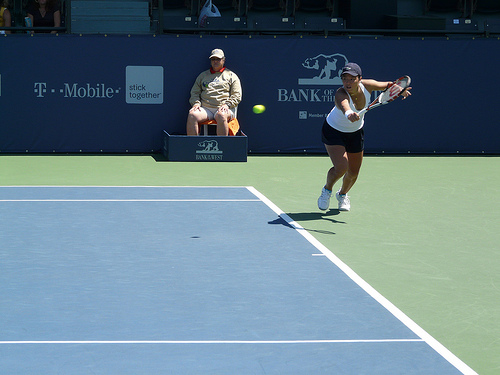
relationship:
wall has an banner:
[1, 34, 499, 154] [34, 82, 119, 100]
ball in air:
[252, 104, 265, 114] [1, 2, 496, 371]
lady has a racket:
[320, 63, 411, 211] [357, 74, 410, 119]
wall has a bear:
[1, 34, 499, 154] [302, 53, 349, 78]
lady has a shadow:
[320, 63, 411, 211] [269, 208, 345, 235]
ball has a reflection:
[252, 104, 265, 114] [192, 234, 202, 240]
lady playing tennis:
[320, 63, 411, 211] [253, 63, 412, 210]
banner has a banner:
[34, 82, 119, 97] [34, 82, 119, 100]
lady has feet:
[320, 63, 411, 211] [318, 187, 332, 211]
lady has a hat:
[320, 63, 411, 211] [341, 62, 362, 77]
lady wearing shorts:
[320, 63, 411, 211] [322, 116, 364, 153]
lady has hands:
[320, 63, 411, 211] [348, 112, 361, 122]